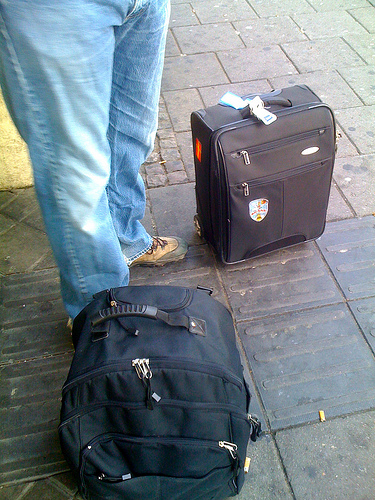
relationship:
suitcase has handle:
[191, 85, 338, 267] [242, 98, 293, 116]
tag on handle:
[249, 103, 275, 126] [242, 98, 293, 116]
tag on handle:
[220, 90, 249, 110] [242, 98, 293, 116]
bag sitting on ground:
[57, 286, 262, 500] [0, 2, 374, 499]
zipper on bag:
[130, 356, 152, 379] [57, 286, 262, 500]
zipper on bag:
[219, 438, 240, 459] [57, 286, 262, 500]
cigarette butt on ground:
[319, 409, 327, 421] [0, 2, 374, 499]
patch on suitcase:
[193, 137, 201, 161] [191, 85, 338, 267]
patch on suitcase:
[248, 198, 269, 223] [191, 85, 338, 267]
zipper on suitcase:
[240, 150, 251, 166] [191, 85, 338, 267]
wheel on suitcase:
[192, 214, 204, 239] [191, 85, 338, 267]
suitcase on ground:
[191, 85, 338, 267] [0, 2, 374, 499]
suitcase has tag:
[191, 85, 338, 267] [249, 103, 275, 126]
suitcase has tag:
[191, 85, 338, 267] [220, 90, 249, 110]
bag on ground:
[57, 286, 262, 500] [0, 2, 374, 499]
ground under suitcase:
[0, 2, 374, 499] [191, 85, 338, 267]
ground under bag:
[0, 2, 374, 499] [57, 286, 262, 500]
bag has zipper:
[57, 286, 262, 500] [130, 356, 152, 379]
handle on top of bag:
[89, 304, 208, 340] [57, 286, 262, 500]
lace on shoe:
[145, 237, 166, 255] [130, 236, 188, 268]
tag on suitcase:
[249, 103, 275, 126] [191, 85, 338, 267]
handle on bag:
[89, 304, 208, 340] [57, 286, 262, 500]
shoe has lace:
[130, 236, 188, 268] [145, 237, 166, 255]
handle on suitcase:
[242, 98, 293, 116] [191, 85, 338, 267]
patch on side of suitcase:
[193, 137, 201, 161] [191, 85, 338, 267]